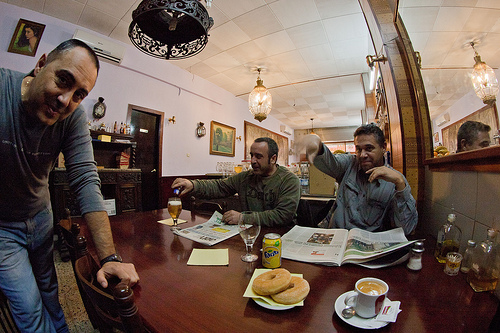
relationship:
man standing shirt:
[0, 29, 134, 333] [1, 64, 111, 226]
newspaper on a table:
[280, 224, 419, 269] [169, 263, 234, 300]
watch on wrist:
[89, 252, 132, 268] [95, 250, 120, 267]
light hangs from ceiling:
[242, 80, 278, 122] [251, 46, 298, 82]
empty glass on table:
[235, 210, 264, 267] [153, 268, 244, 326]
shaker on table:
[406, 237, 427, 270] [114, 121, 474, 317]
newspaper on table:
[280, 224, 419, 269] [84, 204, 499, 331]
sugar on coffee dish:
[378, 303, 403, 321] [335, 280, 399, 330]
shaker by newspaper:
[406, 237, 427, 270] [278, 219, 418, 273]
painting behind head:
[8, 19, 46, 56] [26, 38, 99, 125]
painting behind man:
[8, 19, 46, 56] [0, 29, 134, 333]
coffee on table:
[361, 279, 381, 299] [84, 204, 499, 331]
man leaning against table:
[5, 29, 134, 331] [60, 203, 189, 331]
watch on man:
[88, 244, 138, 279] [35, 43, 167, 260]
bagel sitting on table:
[257, 269, 308, 302] [50, 198, 427, 328]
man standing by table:
[0, 29, 134, 333] [84, 204, 499, 331]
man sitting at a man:
[167, 136, 297, 226] [283, 120, 420, 240]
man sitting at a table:
[167, 136, 297, 226] [84, 204, 499, 331]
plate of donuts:
[251, 272, 299, 312] [250, 269, 312, 304]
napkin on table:
[185, 245, 227, 267] [111, 209, 248, 331]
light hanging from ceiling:
[242, 80, 278, 122] [0, 0, 499, 129]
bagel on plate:
[257, 269, 308, 302] [251, 299, 294, 309]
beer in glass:
[166, 199, 183, 220] [165, 192, 185, 231]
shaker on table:
[406, 237, 427, 270] [84, 204, 499, 331]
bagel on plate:
[257, 269, 308, 302] [254, 273, 306, 311]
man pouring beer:
[167, 136, 297, 226] [166, 199, 183, 220]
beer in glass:
[166, 199, 183, 220] [161, 187, 195, 243]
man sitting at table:
[295, 121, 421, 238] [84, 204, 499, 331]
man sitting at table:
[167, 136, 297, 226] [84, 204, 499, 331]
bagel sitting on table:
[257, 269, 308, 302] [84, 204, 499, 331]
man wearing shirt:
[209, 141, 298, 231] [190, 165, 301, 231]